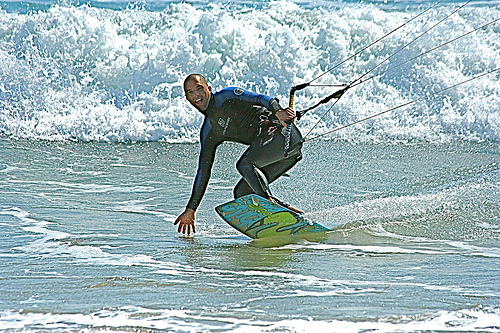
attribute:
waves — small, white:
[128, 246, 365, 300]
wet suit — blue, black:
[186, 86, 304, 217]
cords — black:
[277, 4, 482, 168]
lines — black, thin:
[302, 4, 483, 143]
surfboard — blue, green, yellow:
[212, 191, 329, 241]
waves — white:
[2, 1, 484, 154]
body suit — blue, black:
[183, 86, 303, 222]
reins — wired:
[300, 2, 484, 147]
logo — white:
[213, 113, 233, 143]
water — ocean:
[5, 5, 495, 328]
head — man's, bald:
[177, 68, 210, 108]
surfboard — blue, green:
[217, 185, 332, 245]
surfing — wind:
[4, 4, 494, 330]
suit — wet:
[183, 94, 309, 212]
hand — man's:
[174, 209, 202, 236]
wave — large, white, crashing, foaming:
[4, 3, 494, 156]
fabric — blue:
[213, 85, 282, 108]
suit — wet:
[184, 86, 314, 215]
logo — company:
[208, 110, 235, 143]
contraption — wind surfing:
[270, 5, 499, 175]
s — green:
[252, 210, 319, 250]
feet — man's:
[234, 192, 303, 221]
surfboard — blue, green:
[210, 191, 346, 244]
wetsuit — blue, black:
[184, 88, 313, 218]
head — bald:
[182, 72, 212, 112]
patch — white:
[232, 86, 246, 96]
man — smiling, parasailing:
[172, 70, 306, 235]